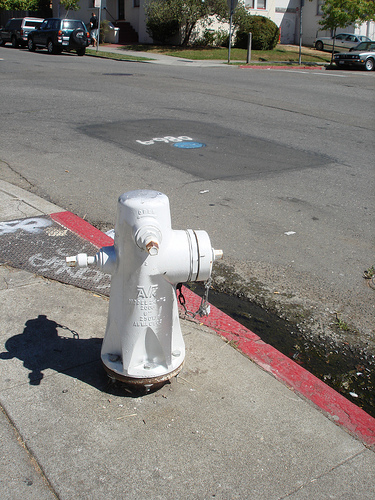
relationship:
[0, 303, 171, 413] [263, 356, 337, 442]
shadow of fire hydrant on sidewalk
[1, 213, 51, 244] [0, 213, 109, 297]
spray paint on metal grate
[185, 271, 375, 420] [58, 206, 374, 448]
puddle next to red marked curb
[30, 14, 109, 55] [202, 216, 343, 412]
cars parked on roadside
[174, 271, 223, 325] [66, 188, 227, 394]
chain hanging from fire hydrant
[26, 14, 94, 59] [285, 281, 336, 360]
cars on side of road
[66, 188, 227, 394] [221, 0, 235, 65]
fire hydrant back of a stop sign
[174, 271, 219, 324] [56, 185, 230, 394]
chain on hydrant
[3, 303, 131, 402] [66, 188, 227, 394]
shadow of fire hydrant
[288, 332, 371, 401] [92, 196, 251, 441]
puddle next to fire hydrant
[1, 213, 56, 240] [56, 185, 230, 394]
spray paint behind hydrant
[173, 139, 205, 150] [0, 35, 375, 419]
blue cover in road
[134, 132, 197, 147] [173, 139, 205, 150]
marking next to blue cover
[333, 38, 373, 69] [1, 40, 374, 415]
car by street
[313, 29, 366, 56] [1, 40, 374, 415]
car by street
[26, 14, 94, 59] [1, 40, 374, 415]
cars by street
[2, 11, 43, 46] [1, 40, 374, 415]
car by street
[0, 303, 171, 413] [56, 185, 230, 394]
shadow of hydrant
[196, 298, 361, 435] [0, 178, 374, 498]
line on sidewalk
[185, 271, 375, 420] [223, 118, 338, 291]
puddle on road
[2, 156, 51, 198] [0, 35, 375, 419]
crack in road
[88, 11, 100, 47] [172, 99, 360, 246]
person in street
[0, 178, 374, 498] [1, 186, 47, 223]
sidewalk has crack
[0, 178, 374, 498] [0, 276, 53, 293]
sidewalk has crack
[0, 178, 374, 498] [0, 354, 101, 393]
sidewalk has crack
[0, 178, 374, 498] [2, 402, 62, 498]
sidewalk has sidewalk line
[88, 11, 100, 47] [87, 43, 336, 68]
person on sidewalk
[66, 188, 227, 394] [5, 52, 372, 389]
fire hydrant on road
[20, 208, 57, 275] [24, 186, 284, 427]
graffiti on sidewalk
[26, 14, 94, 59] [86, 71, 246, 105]
cars on road